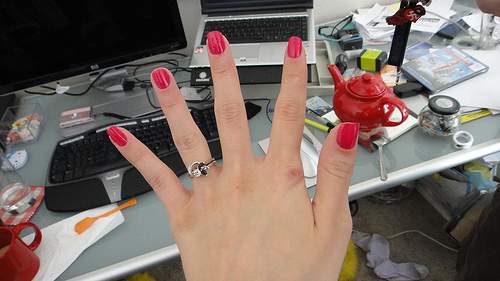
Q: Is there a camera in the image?
A: No, there are no cameras.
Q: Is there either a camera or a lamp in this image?
A: No, there are no cameras or lamps.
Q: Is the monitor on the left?
A: Yes, the monitor is on the left of the image.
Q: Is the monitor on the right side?
A: No, the monitor is on the left of the image.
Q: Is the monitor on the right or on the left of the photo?
A: The monitor is on the left of the image.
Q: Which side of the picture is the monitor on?
A: The monitor is on the left of the image.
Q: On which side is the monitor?
A: The monitor is on the left of the image.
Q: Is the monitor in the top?
A: Yes, the monitor is in the top of the image.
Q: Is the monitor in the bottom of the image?
A: No, the monitor is in the top of the image.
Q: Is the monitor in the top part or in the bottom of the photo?
A: The monitor is in the top of the image.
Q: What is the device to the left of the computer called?
A: The device is a monitor.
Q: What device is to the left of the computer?
A: The device is a monitor.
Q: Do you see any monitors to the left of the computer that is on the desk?
A: Yes, there is a monitor to the left of the computer.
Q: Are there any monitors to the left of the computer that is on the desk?
A: Yes, there is a monitor to the left of the computer.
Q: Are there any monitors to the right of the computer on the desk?
A: No, the monitor is to the left of the computer.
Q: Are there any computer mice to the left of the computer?
A: No, there is a monitor to the left of the computer.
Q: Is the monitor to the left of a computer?
A: Yes, the monitor is to the left of a computer.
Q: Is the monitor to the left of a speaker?
A: No, the monitor is to the left of a computer.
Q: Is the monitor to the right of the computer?
A: No, the monitor is to the left of the computer.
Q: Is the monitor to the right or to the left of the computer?
A: The monitor is to the left of the computer.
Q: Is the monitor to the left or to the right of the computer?
A: The monitor is to the left of the computer.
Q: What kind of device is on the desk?
A: The device is a monitor.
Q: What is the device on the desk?
A: The device is a monitor.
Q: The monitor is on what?
A: The monitor is on the desk.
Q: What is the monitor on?
A: The monitor is on the desk.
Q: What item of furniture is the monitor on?
A: The monitor is on the desk.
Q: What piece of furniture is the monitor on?
A: The monitor is on the desk.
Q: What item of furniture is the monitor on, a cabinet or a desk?
A: The monitor is on a desk.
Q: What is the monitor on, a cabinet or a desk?
A: The monitor is on a desk.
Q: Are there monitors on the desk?
A: Yes, there is a monitor on the desk.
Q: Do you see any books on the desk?
A: No, there is a monitor on the desk.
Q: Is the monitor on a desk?
A: Yes, the monitor is on a desk.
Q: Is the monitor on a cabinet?
A: No, the monitor is on a desk.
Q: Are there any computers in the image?
A: Yes, there is a computer.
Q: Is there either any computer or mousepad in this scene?
A: Yes, there is a computer.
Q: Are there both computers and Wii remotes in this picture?
A: No, there is a computer but no Wii controllers.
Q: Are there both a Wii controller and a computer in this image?
A: No, there is a computer but no Wii controllers.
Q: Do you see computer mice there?
A: No, there are no computer mice.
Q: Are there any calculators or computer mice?
A: No, there are no computer mice or calculators.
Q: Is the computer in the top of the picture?
A: Yes, the computer is in the top of the image.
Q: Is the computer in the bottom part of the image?
A: No, the computer is in the top of the image.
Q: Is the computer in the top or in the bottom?
A: The computer is in the top of the image.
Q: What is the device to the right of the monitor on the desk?
A: The device is a computer.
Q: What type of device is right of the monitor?
A: The device is a computer.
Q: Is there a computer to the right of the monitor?
A: Yes, there is a computer to the right of the monitor.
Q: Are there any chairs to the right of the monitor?
A: No, there is a computer to the right of the monitor.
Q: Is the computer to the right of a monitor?
A: Yes, the computer is to the right of a monitor.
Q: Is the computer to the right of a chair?
A: No, the computer is to the right of a monitor.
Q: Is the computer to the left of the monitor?
A: No, the computer is to the right of the monitor.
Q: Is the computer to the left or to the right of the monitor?
A: The computer is to the right of the monitor.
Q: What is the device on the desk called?
A: The device is a computer.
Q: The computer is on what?
A: The computer is on the desk.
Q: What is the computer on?
A: The computer is on the desk.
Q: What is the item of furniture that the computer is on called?
A: The piece of furniture is a desk.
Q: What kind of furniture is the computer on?
A: The computer is on the desk.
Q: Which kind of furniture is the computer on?
A: The computer is on the desk.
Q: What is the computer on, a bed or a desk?
A: The computer is on a desk.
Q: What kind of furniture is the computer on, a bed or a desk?
A: The computer is on a desk.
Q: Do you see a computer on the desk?
A: Yes, there is a computer on the desk.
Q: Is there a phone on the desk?
A: No, there is a computer on the desk.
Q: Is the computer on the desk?
A: Yes, the computer is on the desk.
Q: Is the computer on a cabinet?
A: No, the computer is on the desk.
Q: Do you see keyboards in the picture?
A: Yes, there is a keyboard.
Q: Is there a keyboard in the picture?
A: Yes, there is a keyboard.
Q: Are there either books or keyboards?
A: Yes, there is a keyboard.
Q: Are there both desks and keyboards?
A: Yes, there are both a keyboard and a desk.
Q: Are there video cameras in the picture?
A: No, there are no video cameras.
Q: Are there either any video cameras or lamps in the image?
A: No, there are no video cameras or lamps.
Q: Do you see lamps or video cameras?
A: No, there are no video cameras or lamps.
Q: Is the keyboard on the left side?
A: Yes, the keyboard is on the left of the image.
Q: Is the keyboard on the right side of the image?
A: No, the keyboard is on the left of the image.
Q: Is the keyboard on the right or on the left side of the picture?
A: The keyboard is on the left of the image.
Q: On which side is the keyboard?
A: The keyboard is on the left of the image.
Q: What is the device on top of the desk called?
A: The device is a keyboard.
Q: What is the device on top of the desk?
A: The device is a keyboard.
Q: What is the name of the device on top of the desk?
A: The device is a keyboard.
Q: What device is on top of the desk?
A: The device is a keyboard.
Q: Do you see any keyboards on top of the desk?
A: Yes, there is a keyboard on top of the desk.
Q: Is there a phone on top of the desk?
A: No, there is a keyboard on top of the desk.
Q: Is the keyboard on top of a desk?
A: Yes, the keyboard is on top of a desk.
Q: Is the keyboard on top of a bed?
A: No, the keyboard is on top of a desk.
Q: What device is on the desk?
A: The device is a keyboard.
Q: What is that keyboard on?
A: The keyboard is on the desk.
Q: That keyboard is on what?
A: The keyboard is on the desk.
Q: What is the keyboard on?
A: The keyboard is on the desk.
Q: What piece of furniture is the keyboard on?
A: The keyboard is on the desk.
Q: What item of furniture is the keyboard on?
A: The keyboard is on the desk.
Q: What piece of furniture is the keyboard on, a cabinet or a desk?
A: The keyboard is on a desk.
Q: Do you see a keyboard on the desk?
A: Yes, there is a keyboard on the desk.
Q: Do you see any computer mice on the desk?
A: No, there is a keyboard on the desk.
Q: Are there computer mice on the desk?
A: No, there is a keyboard on the desk.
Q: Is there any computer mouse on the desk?
A: No, there is a keyboard on the desk.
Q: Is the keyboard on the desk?
A: Yes, the keyboard is on the desk.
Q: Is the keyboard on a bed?
A: No, the keyboard is on the desk.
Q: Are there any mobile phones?
A: No, there are no mobile phones.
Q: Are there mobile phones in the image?
A: No, there are no mobile phones.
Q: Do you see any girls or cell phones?
A: No, there are no cell phones or girls.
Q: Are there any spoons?
A: Yes, there is a spoon.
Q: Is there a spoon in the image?
A: Yes, there is a spoon.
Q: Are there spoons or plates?
A: Yes, there is a spoon.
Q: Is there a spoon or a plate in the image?
A: Yes, there is a spoon.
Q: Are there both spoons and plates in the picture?
A: No, there is a spoon but no plates.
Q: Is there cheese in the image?
A: No, there is no cheese.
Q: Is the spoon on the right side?
A: Yes, the spoon is on the right of the image.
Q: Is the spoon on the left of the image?
A: No, the spoon is on the right of the image.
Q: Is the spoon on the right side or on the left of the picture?
A: The spoon is on the right of the image.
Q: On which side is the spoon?
A: The spoon is on the right of the image.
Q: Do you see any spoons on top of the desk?
A: Yes, there is a spoon on top of the desk.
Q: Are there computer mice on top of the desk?
A: No, there is a spoon on top of the desk.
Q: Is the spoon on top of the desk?
A: Yes, the spoon is on top of the desk.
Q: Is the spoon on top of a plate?
A: No, the spoon is on top of the desk.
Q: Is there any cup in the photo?
A: Yes, there is a cup.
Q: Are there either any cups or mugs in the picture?
A: Yes, there is a cup.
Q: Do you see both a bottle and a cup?
A: No, there is a cup but no bottles.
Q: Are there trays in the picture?
A: No, there are no trays.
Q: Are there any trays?
A: No, there are no trays.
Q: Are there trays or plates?
A: No, there are no trays or plates.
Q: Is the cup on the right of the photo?
A: No, the cup is on the left of the image.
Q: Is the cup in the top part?
A: No, the cup is in the bottom of the image.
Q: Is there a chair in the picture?
A: No, there are no chairs.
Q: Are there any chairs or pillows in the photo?
A: No, there are no chairs or pillows.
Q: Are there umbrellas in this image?
A: No, there are no umbrellas.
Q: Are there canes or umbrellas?
A: No, there are no umbrellas or canes.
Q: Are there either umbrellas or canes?
A: No, there are no umbrellas or canes.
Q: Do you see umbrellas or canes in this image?
A: No, there are no umbrellas or canes.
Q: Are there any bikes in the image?
A: No, there are no bikes.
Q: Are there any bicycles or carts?
A: No, there are no bicycles or carts.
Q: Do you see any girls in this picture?
A: No, there are no girls.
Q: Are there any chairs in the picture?
A: No, there are no chairs.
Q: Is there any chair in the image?
A: No, there are no chairs.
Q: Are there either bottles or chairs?
A: No, there are no chairs or bottles.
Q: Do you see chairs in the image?
A: No, there are no chairs.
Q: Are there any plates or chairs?
A: No, there are no chairs or plates.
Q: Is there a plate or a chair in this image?
A: No, there are no chairs or plates.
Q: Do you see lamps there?
A: No, there are no lamps.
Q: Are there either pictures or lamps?
A: No, there are no lamps or pictures.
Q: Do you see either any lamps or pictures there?
A: No, there are no lamps or pictures.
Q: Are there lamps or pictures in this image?
A: No, there are no lamps or pictures.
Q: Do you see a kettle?
A: Yes, there is a kettle.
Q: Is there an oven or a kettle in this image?
A: Yes, there is a kettle.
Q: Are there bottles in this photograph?
A: No, there are no bottles.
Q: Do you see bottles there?
A: No, there are no bottles.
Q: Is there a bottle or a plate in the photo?
A: No, there are no bottles or plates.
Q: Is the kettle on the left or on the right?
A: The kettle is on the right of the image.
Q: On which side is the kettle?
A: The kettle is on the right of the image.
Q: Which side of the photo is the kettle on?
A: The kettle is on the right of the image.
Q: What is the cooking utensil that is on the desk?
A: The cooking utensil is a kettle.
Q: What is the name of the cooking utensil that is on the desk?
A: The cooking utensil is a kettle.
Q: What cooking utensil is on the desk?
A: The cooking utensil is a kettle.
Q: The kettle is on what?
A: The kettle is on the desk.